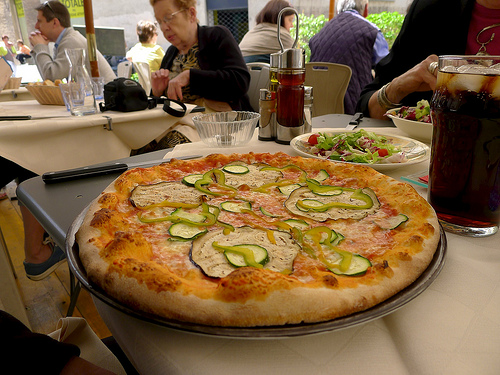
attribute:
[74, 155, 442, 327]
pizza — round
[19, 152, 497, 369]
table — grey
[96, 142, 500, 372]
tablecloth — white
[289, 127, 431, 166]
plate — white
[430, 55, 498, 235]
soda — dark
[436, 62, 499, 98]
cubes — ice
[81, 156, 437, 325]
crust — toasted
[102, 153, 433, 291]
cheese — yellow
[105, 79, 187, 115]
bag — black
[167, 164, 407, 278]
vegetables — sliced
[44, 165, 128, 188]
handle — black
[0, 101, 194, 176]
cloth — tan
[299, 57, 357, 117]
chair — tan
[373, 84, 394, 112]
bracelets — silver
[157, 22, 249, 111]
sweater — black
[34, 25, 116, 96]
shirt — gray